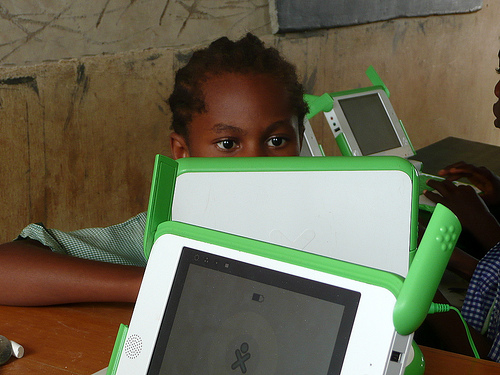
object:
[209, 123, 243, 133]
eye brow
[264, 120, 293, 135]
eye brow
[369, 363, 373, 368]
spot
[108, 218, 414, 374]
tablet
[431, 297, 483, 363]
cord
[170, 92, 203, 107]
braid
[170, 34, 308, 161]
head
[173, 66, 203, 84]
braid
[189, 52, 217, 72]
braid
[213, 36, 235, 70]
braid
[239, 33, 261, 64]
braid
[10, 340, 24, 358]
chalk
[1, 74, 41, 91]
dent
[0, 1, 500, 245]
wall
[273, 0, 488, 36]
screen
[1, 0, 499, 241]
board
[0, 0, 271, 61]
marks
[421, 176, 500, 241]
hand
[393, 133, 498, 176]
table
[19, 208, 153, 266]
shirt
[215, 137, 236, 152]
eye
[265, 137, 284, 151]
eye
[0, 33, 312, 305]
boy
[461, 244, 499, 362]
shirt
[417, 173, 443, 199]
keyboard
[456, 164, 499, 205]
hand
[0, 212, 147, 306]
arm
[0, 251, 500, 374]
table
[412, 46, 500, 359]
kid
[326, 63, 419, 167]
cpu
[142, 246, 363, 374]
cpu screen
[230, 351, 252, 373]
x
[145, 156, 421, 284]
monitor